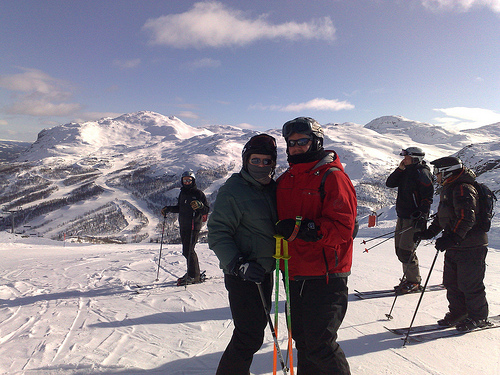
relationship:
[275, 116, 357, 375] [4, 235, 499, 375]
man standing on a ski slope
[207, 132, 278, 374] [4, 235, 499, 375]
woman standing on a ski slope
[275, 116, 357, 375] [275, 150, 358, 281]
man wearing a ski coat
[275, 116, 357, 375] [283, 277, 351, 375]
man wearing ski pants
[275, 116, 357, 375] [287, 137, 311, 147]
man wearing sunglasses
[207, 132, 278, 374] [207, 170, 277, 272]
woman wearing a ski coat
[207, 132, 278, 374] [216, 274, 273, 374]
woman wearing ski pants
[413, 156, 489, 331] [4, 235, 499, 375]
man on ski slope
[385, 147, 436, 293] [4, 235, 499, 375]
person on ski slope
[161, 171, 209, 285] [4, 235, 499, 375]
person on ski slope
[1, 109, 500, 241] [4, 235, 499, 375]
mountains behind ski slope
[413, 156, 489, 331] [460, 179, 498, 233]
man wearing backpack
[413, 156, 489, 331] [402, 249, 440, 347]
man holding ski pole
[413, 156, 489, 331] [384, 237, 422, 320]
man holding ski pole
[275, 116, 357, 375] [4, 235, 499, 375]
man on top of ski slope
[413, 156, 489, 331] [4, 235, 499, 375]
man on top of ski slope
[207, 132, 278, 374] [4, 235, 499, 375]
woman on top of ski slope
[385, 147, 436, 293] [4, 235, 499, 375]
person on top of ski slope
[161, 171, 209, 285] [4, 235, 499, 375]
person on top of ski slope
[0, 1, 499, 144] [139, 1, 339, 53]
sky has cloud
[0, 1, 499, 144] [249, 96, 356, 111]
sky has cloud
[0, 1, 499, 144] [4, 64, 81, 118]
sky has cloud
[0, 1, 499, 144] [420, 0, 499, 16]
sky has cloud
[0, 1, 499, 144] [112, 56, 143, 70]
sky has cloud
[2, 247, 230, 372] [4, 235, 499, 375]
ski tracks on ski slope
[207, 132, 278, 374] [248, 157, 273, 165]
woman wearing sunglasses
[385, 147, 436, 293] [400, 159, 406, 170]
person has hand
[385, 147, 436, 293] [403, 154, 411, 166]
person has face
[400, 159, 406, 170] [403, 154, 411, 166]
hand held up to face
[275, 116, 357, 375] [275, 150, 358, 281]
man wearing ski coat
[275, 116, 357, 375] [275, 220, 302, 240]
man has hand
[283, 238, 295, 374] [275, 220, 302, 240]
ski pole held in hand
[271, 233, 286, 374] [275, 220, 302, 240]
ski pole held in hand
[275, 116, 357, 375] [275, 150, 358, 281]
man in ski coat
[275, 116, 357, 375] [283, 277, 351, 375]
man in ski pants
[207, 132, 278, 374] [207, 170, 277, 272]
woman in ski coat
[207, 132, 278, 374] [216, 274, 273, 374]
woman in ski pants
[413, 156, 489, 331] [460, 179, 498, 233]
man carrying backpack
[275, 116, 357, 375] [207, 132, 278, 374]
man standing next to woman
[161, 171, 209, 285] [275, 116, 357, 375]
person looking at man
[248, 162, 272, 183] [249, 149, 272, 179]
scarf covering half of face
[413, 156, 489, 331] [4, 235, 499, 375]
man looking down ski slope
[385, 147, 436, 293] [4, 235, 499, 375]
person looking down ski slope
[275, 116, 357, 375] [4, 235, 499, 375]
man on ski slope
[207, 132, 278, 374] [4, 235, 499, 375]
woman on ski slope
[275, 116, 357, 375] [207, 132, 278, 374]
man posing next to woman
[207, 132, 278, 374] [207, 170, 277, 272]
woman with a ski coat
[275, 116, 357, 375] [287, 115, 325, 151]
man wearing helmet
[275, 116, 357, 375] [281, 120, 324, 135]
man wearing goggles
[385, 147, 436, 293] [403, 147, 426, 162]
person wearing helmet